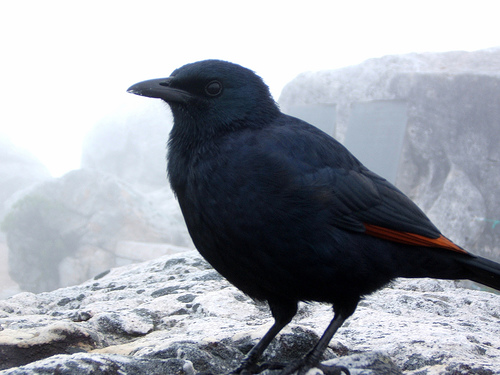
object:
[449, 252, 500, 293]
tail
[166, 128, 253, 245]
chest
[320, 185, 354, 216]
feathers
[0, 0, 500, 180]
sky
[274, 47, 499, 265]
craggy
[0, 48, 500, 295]
mountain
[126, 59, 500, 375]
bird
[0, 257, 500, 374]
ground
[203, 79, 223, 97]
eye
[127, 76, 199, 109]
beak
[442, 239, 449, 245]
red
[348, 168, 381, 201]
feather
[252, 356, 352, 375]
feet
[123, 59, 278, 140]
head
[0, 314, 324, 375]
rocks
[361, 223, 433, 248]
red feathers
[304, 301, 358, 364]
legs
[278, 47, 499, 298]
carved surface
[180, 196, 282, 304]
belly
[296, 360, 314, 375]
claw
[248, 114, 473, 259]
wing